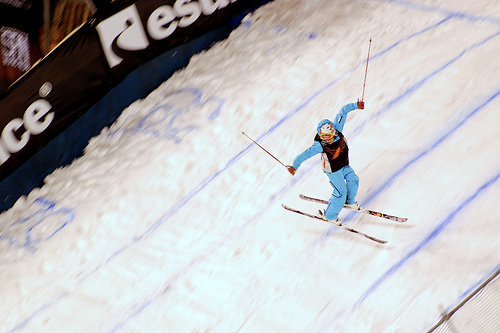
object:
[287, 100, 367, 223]
person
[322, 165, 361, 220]
ski pants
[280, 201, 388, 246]
ski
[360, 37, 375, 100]
ski pole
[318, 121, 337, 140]
helmet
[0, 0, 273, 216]
net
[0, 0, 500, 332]
snow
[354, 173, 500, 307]
line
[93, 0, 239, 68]
writing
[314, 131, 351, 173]
suit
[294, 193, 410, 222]
left ski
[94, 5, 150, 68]
company logo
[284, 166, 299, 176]
glove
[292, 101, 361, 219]
ski suit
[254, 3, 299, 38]
track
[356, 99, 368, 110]
hand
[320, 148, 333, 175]
edge